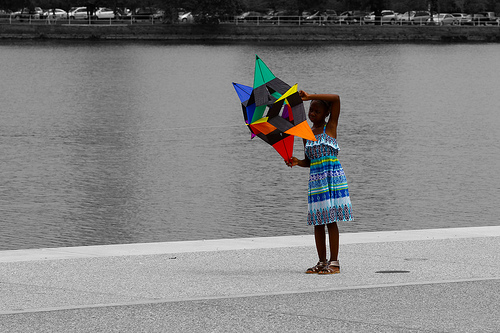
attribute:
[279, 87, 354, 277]
girl — little, young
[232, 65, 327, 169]
kite — different colors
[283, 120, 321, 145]
triangle — orange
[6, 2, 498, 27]
cars — parked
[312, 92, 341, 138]
arm — bent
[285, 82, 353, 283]
girl — standing, holding kite, little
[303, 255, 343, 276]
sandles — gold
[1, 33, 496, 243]
water — clear, calm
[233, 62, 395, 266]
girl — little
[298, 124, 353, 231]
dress — blue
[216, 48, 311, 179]
kite — colorful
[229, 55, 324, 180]
kite — colorful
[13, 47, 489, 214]
water — calm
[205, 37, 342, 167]
kite — colorful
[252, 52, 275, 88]
triangle — green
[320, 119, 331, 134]
strap — thin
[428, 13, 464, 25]
cars — parked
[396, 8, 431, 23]
cars — parked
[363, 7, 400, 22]
cars — parked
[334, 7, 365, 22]
cars — parked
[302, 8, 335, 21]
cars — parked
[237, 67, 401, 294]
girl — young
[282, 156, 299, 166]
hand — girl's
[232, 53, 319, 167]
kite — multi-colored, multicolored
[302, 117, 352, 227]
dress — colorful